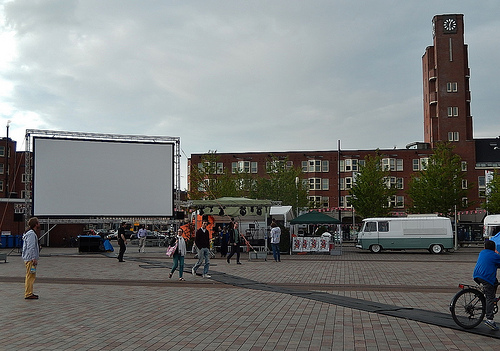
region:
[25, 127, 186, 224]
large white projection screen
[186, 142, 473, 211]
red brick building with white windows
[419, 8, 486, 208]
tall red clock tower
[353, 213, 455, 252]
grey and white van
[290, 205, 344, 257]
dark green tent top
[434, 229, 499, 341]
boy wearing blue shirt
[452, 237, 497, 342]
boy riding a bicycle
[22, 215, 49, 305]
man wearing yellow pants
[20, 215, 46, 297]
man in grey shirt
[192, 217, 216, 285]
man in black sweater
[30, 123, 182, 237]
large white bare billboard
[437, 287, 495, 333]
black bicycle wheel with spokes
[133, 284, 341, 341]
line in tiles on ground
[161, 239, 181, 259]
pink bag over woman's shoulder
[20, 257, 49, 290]
man wearing yellow pants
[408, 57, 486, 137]
large brown tower building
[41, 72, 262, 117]
dark clouds in the sky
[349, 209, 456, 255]
white and blue van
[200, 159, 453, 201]
cluster of green trees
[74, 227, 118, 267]
black table with blue top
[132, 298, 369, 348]
Street made of bricks.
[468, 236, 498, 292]
A person in a blue jacket.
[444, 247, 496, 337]
The back wheel of a bicycle.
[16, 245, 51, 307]
A pair of yellow pants.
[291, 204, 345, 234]
A green tent awning.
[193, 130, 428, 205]
Red building in background.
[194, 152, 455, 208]
Green trees in background.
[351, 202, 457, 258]
A white and grey van.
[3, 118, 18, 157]
A smokestack on a building.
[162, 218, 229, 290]
Two people walking.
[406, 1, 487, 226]
Tall brick building with white windows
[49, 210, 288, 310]
People walking on street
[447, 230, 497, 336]
Person riding a bike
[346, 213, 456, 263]
Green and white bus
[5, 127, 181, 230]
Blank white billboard in center of town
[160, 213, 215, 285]
Man and woman walking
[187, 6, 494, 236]
Red brick building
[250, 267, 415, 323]
Black mats on the street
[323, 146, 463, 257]
Tall green trees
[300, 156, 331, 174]
Four white windows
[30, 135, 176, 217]
Large white screen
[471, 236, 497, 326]
Person in blue who is leaving the screen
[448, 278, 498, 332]
Bicycle of the person in blue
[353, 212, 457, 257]
Parked Green and white van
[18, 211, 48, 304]
Person in the yellow pants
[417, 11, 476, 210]
The red tower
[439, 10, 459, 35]
Clock at the top of the red tower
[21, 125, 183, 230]
Metal frame around the large white screen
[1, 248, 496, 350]
Brick walkway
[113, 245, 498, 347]
Black rubber mats that cover cables